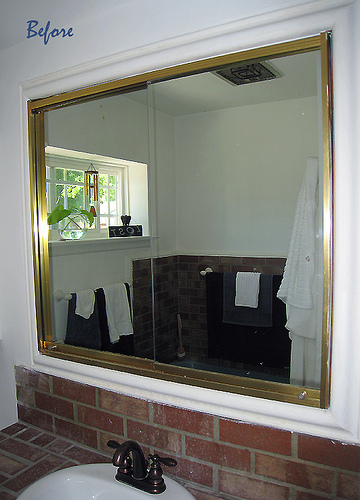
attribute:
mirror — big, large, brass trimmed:
[27, 27, 333, 410]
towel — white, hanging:
[232, 273, 261, 313]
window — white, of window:
[44, 149, 149, 238]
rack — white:
[55, 277, 134, 302]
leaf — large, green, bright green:
[48, 205, 71, 229]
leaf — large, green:
[74, 206, 95, 229]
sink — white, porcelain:
[23, 457, 202, 499]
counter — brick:
[1, 421, 359, 500]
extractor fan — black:
[210, 62, 288, 89]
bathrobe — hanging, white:
[278, 157, 321, 391]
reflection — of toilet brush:
[173, 312, 189, 361]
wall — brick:
[132, 251, 287, 377]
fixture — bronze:
[104, 439, 177, 499]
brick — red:
[50, 377, 97, 405]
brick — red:
[75, 406, 126, 438]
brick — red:
[214, 418, 293, 450]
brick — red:
[181, 434, 252, 476]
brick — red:
[292, 432, 358, 475]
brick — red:
[32, 390, 76, 420]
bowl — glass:
[58, 211, 87, 241]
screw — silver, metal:
[297, 388, 308, 404]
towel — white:
[101, 283, 136, 343]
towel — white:
[71, 288, 96, 322]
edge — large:
[47, 234, 147, 255]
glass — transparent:
[28, 50, 320, 394]